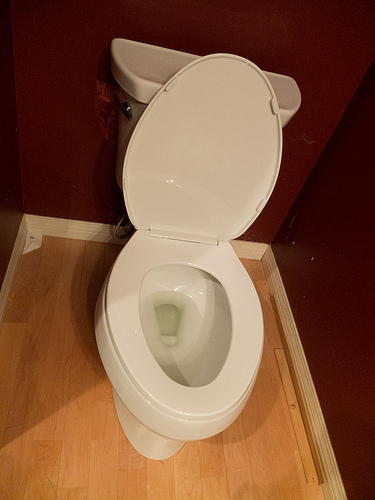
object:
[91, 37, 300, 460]
toilet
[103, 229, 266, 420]
toilet seat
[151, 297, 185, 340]
drain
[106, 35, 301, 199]
toilet tank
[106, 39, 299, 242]
cover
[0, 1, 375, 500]
bathroom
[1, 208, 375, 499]
floor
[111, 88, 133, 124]
flush lever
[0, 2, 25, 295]
right wall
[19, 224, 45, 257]
toilet paper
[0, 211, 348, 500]
paneling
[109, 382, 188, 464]
bottom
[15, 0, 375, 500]
wall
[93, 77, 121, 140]
flaws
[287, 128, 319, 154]
flaws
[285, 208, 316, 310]
flaws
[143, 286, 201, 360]
water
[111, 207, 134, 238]
hose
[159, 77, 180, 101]
hinges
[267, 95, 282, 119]
hinges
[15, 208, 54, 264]
corner